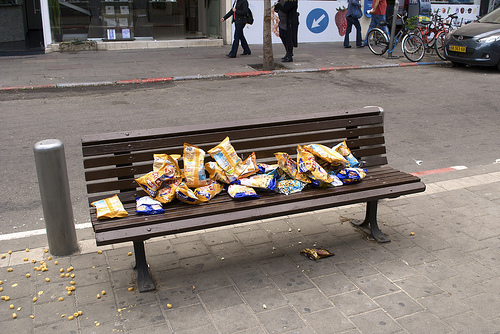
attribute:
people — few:
[225, 4, 385, 51]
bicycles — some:
[374, 24, 445, 60]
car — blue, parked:
[453, 20, 484, 50]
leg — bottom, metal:
[129, 240, 155, 296]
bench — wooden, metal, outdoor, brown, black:
[81, 100, 427, 295]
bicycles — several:
[365, 10, 461, 61]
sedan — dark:
[444, 2, 498, 71]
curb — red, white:
[1, 63, 450, 93]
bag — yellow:
[90, 193, 129, 220]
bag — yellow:
[303, 141, 349, 165]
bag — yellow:
[183, 141, 208, 186]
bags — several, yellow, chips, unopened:
[91, 134, 366, 218]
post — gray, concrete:
[34, 138, 77, 258]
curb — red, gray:
[2, 59, 453, 92]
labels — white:
[104, 5, 131, 40]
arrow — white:
[309, 10, 326, 28]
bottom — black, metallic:
[131, 235, 157, 292]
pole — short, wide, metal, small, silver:
[34, 137, 76, 257]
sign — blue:
[305, 8, 328, 33]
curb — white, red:
[2, 60, 418, 91]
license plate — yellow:
[449, 42, 466, 52]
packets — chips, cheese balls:
[90, 134, 368, 219]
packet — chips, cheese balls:
[273, 178, 306, 193]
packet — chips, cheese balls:
[334, 139, 360, 168]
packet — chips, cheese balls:
[272, 150, 314, 184]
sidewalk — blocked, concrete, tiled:
[1, 162, 499, 330]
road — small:
[1, 62, 499, 251]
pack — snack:
[302, 246, 337, 260]